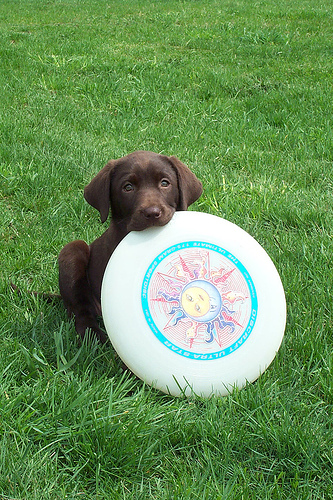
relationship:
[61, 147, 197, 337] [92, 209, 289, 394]
puppy with frisbee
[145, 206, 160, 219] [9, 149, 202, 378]
nose of puppy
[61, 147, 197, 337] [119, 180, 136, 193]
puppy has eye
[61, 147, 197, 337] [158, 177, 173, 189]
puppy has eye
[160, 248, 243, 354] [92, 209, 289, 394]
sun in middle of frisbee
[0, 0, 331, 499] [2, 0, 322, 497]
grass in field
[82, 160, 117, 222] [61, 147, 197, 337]
ear of puppy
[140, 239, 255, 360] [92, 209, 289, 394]
circle in middle of frisbee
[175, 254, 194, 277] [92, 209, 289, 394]
ray on frisbee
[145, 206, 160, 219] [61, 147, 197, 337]
nose of puppy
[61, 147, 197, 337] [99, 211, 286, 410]
puppy holding frisbee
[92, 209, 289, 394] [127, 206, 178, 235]
frisbee in mouth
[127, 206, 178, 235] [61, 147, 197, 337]
mouth of puppy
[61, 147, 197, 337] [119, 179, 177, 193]
puppy has eyes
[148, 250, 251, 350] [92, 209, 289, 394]
logo on frisbee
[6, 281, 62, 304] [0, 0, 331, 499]
tail in grass